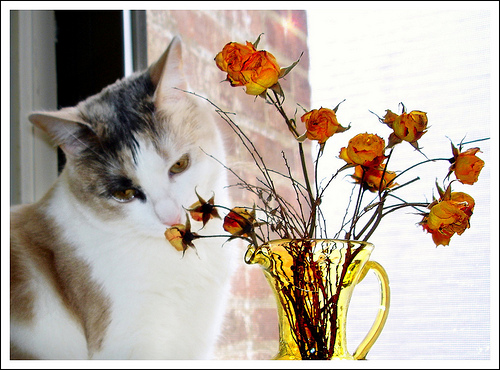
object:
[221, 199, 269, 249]
rose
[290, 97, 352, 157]
rose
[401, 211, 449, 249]
rose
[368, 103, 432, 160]
rose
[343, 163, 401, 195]
rose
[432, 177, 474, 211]
rose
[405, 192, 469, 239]
rose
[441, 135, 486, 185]
rose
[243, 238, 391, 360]
pitcher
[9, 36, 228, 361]
cat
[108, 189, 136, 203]
eye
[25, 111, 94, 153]
ear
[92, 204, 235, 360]
chest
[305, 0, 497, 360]
window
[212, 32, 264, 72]
rose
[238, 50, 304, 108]
rose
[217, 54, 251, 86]
rose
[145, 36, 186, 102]
ear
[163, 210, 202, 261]
nose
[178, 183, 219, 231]
roses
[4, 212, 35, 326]
brown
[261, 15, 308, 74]
bricks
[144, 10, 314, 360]
wall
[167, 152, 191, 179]
eyes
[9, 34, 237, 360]
fur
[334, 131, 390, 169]
flower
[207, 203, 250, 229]
stem